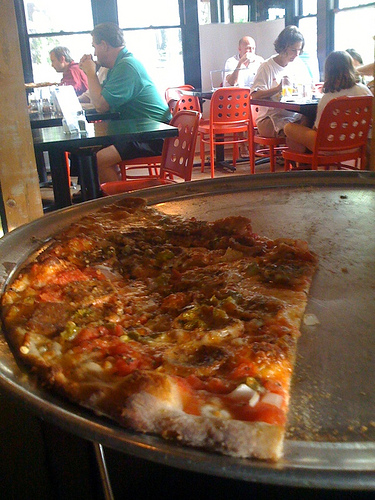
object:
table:
[31, 117, 179, 215]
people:
[248, 24, 373, 170]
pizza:
[1, 195, 321, 462]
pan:
[1, 168, 373, 489]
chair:
[97, 109, 203, 198]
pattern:
[170, 120, 195, 169]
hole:
[175, 121, 183, 131]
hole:
[171, 136, 178, 144]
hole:
[181, 140, 187, 150]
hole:
[187, 142, 192, 151]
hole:
[178, 153, 184, 164]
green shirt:
[98, 46, 174, 134]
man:
[48, 47, 91, 97]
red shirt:
[60, 60, 88, 96]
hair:
[49, 46, 74, 64]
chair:
[198, 87, 254, 179]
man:
[221, 34, 266, 97]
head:
[238, 35, 256, 62]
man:
[76, 22, 176, 191]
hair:
[273, 25, 305, 56]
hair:
[322, 50, 361, 93]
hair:
[90, 23, 125, 47]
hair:
[345, 48, 364, 66]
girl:
[248, 22, 314, 156]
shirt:
[250, 53, 313, 134]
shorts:
[113, 129, 178, 162]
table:
[248, 90, 318, 171]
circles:
[217, 93, 248, 118]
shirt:
[222, 54, 266, 89]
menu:
[46, 84, 91, 135]